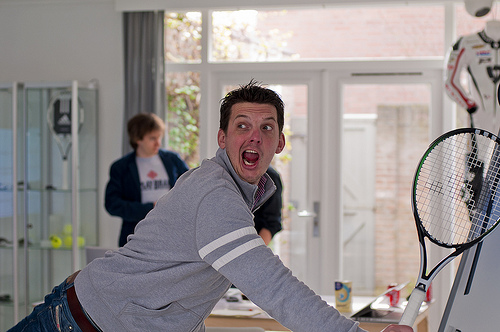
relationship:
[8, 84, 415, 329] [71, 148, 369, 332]
man wearing gray shirt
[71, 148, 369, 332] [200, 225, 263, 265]
gray shirt with stripes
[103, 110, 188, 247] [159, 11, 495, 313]
hipster standing beside window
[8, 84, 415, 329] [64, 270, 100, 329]
man wearing belt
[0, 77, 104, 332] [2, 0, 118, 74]
case against wall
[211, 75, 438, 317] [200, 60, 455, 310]
glass doors with white frames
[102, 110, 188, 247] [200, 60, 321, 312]
hipster near a doorway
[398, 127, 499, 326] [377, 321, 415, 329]
racket in a hand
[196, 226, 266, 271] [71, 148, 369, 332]
stripe on a gray shirt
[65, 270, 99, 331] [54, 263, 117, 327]
belt around a waist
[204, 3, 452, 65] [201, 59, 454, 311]
large window above a doorway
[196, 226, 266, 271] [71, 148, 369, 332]
stripe on gray shirt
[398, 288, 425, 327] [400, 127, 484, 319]
grip on racket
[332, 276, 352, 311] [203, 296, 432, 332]
carton on counter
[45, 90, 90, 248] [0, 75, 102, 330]
items in case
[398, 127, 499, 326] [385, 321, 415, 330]
racket in man's hand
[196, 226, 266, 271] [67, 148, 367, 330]
stripe on gray shirt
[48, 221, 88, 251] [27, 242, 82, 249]
tennis balls on a shelf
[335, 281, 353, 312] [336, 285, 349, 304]
carton with blue swirl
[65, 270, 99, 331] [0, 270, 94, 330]
belt on man's pants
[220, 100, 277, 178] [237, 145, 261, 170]
man's face with mouth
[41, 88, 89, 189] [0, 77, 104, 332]
racket hanging on a case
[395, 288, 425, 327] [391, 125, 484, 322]
grip on racket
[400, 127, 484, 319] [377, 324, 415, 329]
racket in a hand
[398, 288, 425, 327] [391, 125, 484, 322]
grip on a racket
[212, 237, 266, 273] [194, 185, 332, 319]
stripe on a sleeve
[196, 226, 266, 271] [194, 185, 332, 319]
stripe on a sleeve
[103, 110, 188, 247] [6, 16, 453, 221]
hipster in background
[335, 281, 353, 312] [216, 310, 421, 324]
carton on a counter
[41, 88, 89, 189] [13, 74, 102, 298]
racket in a case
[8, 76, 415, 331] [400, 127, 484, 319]
man holding racket